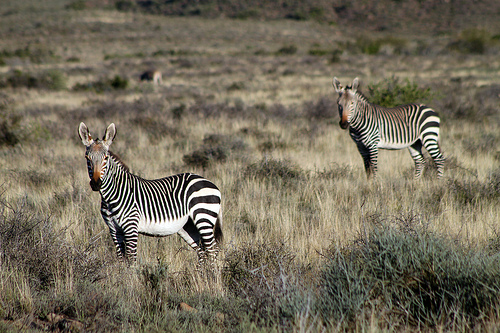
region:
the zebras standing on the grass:
[77, 77, 444, 269]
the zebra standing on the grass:
[76, 120, 221, 265]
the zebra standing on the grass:
[331, 77, 443, 179]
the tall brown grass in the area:
[0, 0, 497, 332]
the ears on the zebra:
[77, 121, 116, 146]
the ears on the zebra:
[332, 76, 359, 91]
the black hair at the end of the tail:
[214, 219, 224, 246]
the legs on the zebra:
[109, 222, 216, 265]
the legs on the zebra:
[360, 143, 443, 180]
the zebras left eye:
[102, 154, 108, 162]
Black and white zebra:
[75, 121, 226, 261]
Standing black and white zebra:
[73, 120, 225, 265]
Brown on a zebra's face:
[74, 120, 119, 192]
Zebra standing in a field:
[331, 75, 446, 178]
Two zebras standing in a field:
[77, 75, 444, 263]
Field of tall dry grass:
[1, 0, 498, 331]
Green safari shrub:
[311, 224, 496, 331]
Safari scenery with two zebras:
[0, 0, 497, 332]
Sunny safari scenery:
[0, 0, 497, 332]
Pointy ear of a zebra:
[77, 120, 91, 147]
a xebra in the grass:
[65, 112, 228, 281]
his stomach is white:
[137, 216, 187, 236]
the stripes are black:
[87, 159, 228, 259]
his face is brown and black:
[70, 115, 119, 193]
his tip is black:
[86, 180, 106, 194]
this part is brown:
[90, 165, 102, 178]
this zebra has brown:
[322, 73, 451, 180]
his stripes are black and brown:
[381, 101, 418, 144]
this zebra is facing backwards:
[137, 63, 164, 88]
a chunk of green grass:
[321, 204, 498, 330]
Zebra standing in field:
[75, 120, 223, 270]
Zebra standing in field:
[330, 71, 445, 178]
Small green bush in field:
[235, 154, 304, 185]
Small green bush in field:
[177, 142, 228, 169]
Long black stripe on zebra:
[135, 176, 147, 223]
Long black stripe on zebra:
[140, 177, 160, 227]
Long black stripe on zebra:
[172, 170, 185, 224]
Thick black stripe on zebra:
[191, 205, 219, 223]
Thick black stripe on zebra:
[187, 190, 222, 208]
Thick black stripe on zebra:
[184, 177, 217, 216]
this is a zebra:
[60, 112, 255, 310]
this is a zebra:
[322, 56, 456, 220]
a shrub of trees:
[142, 257, 217, 331]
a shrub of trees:
[231, 230, 309, 330]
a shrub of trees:
[217, 133, 327, 236]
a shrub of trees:
[39, 232, 96, 305]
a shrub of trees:
[360, 48, 447, 140]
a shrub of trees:
[180, 138, 255, 185]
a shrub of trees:
[24, 58, 83, 99]